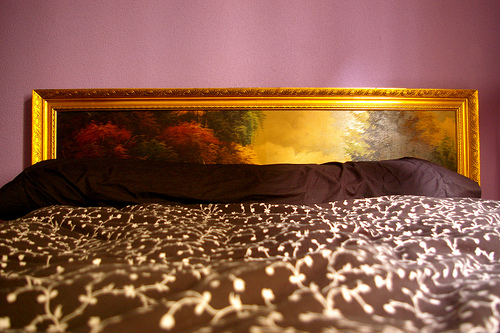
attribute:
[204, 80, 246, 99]
frame — gold, embossed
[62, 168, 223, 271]
bed — large, queen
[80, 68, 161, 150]
photo — artistic, framed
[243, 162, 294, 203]
comforter — brown, here, black, printed, top, gold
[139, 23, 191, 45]
wall — purple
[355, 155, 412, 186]
pillow — brown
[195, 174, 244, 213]
pillow case — here, wrinkled, black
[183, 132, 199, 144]
bush — red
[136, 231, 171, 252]
tree — white, red, yellow, tall, lot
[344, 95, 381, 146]
light — shining